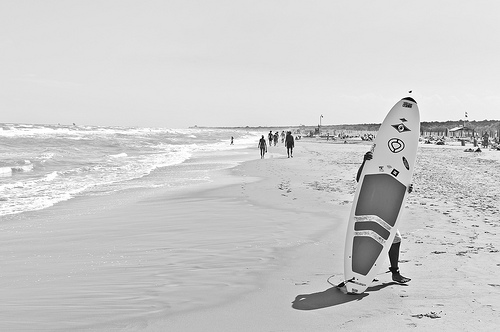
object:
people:
[284, 131, 294, 159]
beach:
[0, 125, 499, 331]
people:
[257, 135, 267, 159]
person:
[357, 143, 416, 287]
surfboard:
[340, 89, 419, 301]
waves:
[5, 123, 219, 137]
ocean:
[0, 122, 264, 220]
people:
[474, 147, 482, 153]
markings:
[391, 123, 412, 134]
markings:
[399, 118, 408, 122]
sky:
[1, 1, 500, 133]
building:
[449, 125, 478, 138]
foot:
[392, 273, 412, 283]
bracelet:
[388, 266, 401, 273]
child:
[229, 136, 235, 146]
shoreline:
[1, 125, 261, 216]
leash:
[376, 268, 391, 276]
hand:
[363, 151, 373, 161]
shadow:
[288, 273, 397, 311]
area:
[269, 122, 500, 208]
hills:
[314, 116, 499, 136]